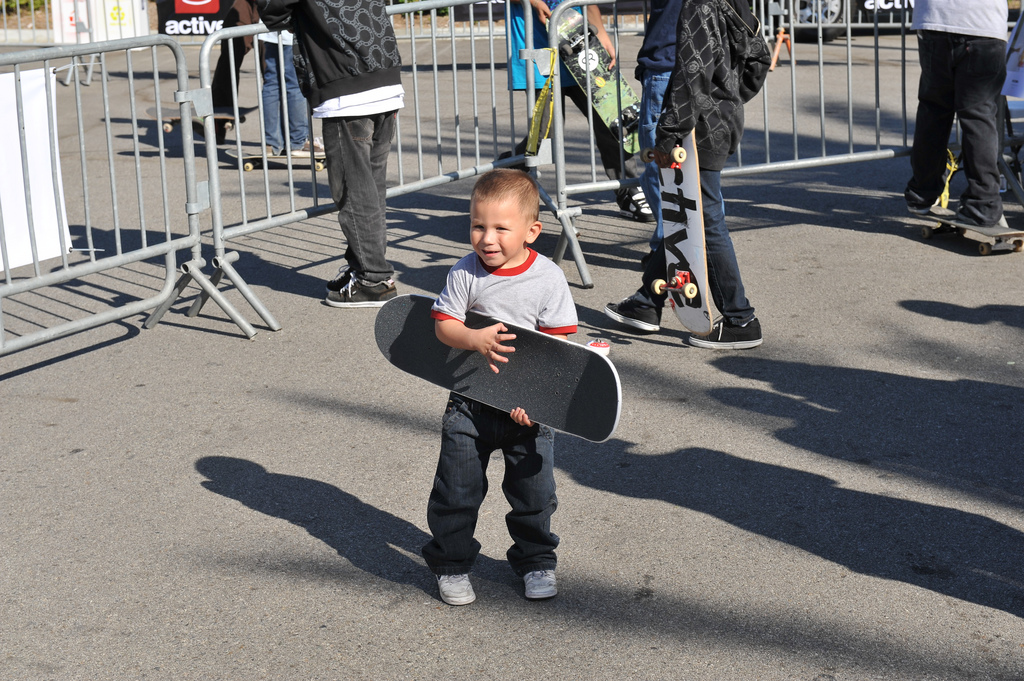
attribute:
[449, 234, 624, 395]
shirt — grey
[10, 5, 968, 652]
scene — outdoor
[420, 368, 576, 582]
pants — blue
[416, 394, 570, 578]
pants — blue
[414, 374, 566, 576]
jeans — blue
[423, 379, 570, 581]
jeans — blue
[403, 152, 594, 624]
boy — little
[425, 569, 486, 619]
shoe — white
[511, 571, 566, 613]
shoe — white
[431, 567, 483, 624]
shoe — white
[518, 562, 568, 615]
shoe — white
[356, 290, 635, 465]
skateboard — black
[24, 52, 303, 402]
fences — gray metal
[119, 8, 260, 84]
sign — black red and white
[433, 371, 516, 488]
shorts — blue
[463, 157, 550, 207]
hair — blond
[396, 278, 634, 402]
wheels — yellow